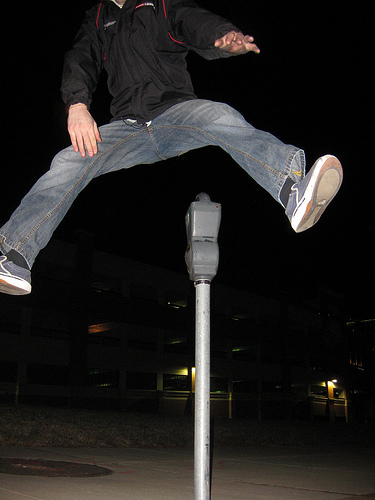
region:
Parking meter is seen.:
[178, 195, 234, 291]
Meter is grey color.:
[182, 208, 222, 341]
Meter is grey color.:
[178, 197, 235, 283]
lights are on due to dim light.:
[164, 352, 198, 498]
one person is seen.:
[49, 46, 234, 139]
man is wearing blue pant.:
[188, 109, 280, 166]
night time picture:
[60, 289, 310, 407]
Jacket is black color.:
[112, 33, 173, 76]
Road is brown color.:
[247, 465, 306, 492]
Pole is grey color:
[193, 288, 226, 499]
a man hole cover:
[1, 452, 112, 480]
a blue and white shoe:
[283, 147, 344, 238]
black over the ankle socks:
[267, 150, 335, 227]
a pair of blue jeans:
[8, 97, 306, 279]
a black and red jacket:
[54, 0, 265, 120]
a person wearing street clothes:
[11, 4, 365, 277]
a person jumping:
[15, 4, 356, 483]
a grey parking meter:
[173, 180, 235, 489]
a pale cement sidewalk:
[224, 445, 352, 489]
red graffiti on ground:
[35, 448, 142, 477]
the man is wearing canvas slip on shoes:
[284, 154, 343, 232]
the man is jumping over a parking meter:
[181, 191, 221, 499]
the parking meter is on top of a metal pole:
[190, 281, 213, 498]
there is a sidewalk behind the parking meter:
[1, 444, 373, 498]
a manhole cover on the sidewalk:
[0, 456, 113, 480]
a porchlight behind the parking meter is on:
[192, 367, 197, 376]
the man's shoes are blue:
[284, 154, 342, 232]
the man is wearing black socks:
[280, 175, 293, 207]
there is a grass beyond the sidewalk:
[0, 403, 335, 449]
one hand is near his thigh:
[65, 103, 106, 156]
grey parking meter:
[183, 189, 217, 497]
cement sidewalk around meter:
[9, 438, 371, 499]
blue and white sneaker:
[283, 151, 343, 233]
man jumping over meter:
[16, 1, 344, 289]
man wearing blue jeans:
[10, 2, 349, 278]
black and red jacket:
[60, 0, 261, 131]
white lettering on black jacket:
[99, 13, 121, 32]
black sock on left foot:
[274, 170, 302, 202]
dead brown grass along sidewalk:
[6, 406, 315, 448]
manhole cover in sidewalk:
[3, 452, 116, 488]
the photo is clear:
[5, 4, 370, 499]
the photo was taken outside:
[2, 4, 374, 498]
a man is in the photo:
[3, 3, 372, 295]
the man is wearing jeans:
[0, 90, 372, 304]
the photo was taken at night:
[1, 2, 373, 315]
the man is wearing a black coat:
[33, 2, 283, 184]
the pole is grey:
[171, 190, 264, 493]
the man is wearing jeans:
[272, 142, 352, 263]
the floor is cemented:
[220, 448, 370, 498]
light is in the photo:
[134, 327, 371, 438]